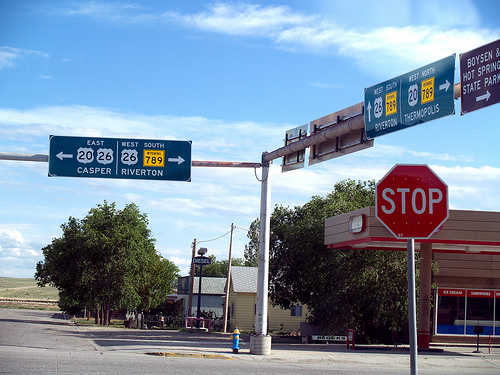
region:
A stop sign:
[374, 162, 449, 238]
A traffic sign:
[47, 134, 193, 184]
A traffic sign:
[360, 52, 455, 139]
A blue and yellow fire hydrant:
[227, 328, 242, 353]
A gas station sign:
[188, 248, 211, 266]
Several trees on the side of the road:
[42, 200, 174, 327]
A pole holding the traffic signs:
[246, 147, 272, 353]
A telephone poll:
[218, 222, 235, 334]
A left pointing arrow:
[53, 149, 77, 162]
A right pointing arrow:
[167, 154, 185, 167]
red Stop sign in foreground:
[375, 160, 440, 240]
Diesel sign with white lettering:
[185, 250, 215, 265]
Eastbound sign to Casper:
[45, 135, 115, 175]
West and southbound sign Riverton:
[115, 140, 190, 175]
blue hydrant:
[225, 320, 240, 350]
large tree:
[35, 200, 190, 320]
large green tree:
[35, 195, 180, 315]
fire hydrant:
[225, 325, 245, 350]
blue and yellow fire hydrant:
[225, 325, 245, 355]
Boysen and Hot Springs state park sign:
[460, 35, 497, 110]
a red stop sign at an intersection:
[370, 155, 451, 371]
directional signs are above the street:
[45, 133, 195, 184]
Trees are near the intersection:
[32, 200, 179, 335]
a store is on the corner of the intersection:
[248, 105, 498, 366]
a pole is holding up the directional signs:
[246, 145, 272, 355]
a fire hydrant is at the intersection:
[226, 322, 241, 353]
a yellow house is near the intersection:
[220, 261, 315, 337]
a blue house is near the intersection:
[163, 271, 224, 334]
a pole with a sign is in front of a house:
[190, 245, 257, 335]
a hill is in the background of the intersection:
[1, 268, 71, 337]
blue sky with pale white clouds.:
[44, 183, 262, 201]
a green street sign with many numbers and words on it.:
[49, 135, 195, 182]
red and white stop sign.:
[368, 160, 454, 238]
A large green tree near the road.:
[32, 197, 181, 326]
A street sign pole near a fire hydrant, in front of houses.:
[195, 146, 277, 356]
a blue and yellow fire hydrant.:
[226, 325, 246, 355]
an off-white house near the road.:
[223, 260, 256, 332]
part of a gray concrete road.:
[3, 327, 230, 372]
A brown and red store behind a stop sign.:
[325, 202, 497, 370]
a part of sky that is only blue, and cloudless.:
[103, 65, 286, 96]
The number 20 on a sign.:
[77, 146, 95, 162]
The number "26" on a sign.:
[96, 148, 116, 163]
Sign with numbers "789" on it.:
[140, 146, 166, 167]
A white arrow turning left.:
[54, 150, 74, 165]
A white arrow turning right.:
[161, 147, 191, 172]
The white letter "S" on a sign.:
[378, 188, 398, 215]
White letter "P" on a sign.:
[426, 186, 440, 214]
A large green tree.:
[51, 220, 158, 313]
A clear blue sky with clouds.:
[0, 3, 302, 93]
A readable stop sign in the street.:
[366, 159, 454, 245]